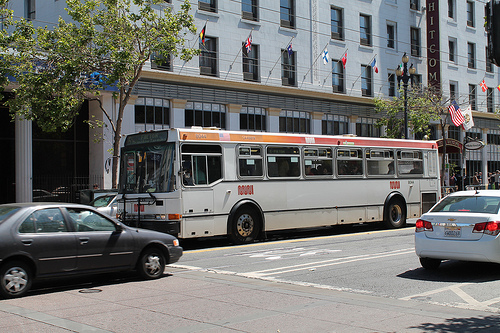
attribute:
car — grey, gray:
[1, 202, 177, 283]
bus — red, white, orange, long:
[120, 129, 439, 226]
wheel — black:
[232, 205, 264, 240]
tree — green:
[10, 10, 178, 189]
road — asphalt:
[4, 237, 500, 331]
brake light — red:
[415, 219, 433, 233]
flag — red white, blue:
[368, 60, 385, 75]